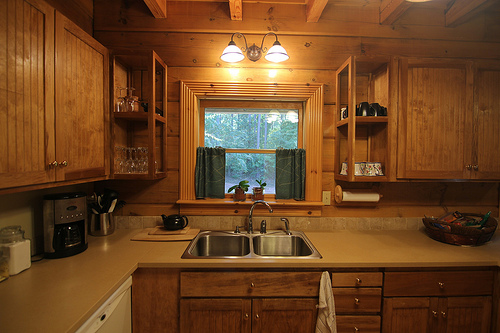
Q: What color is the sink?
A: Silver.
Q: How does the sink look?
A: Clean and polished.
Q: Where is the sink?
A: Between the counter.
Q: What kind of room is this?
A: Kitchen.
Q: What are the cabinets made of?
A: Wood.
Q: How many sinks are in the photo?
A: Two.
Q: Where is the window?
A: Above the sink.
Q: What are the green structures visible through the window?
A: Trees.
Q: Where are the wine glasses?
A: On the shelf to the left of the sink.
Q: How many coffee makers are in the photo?
A: One.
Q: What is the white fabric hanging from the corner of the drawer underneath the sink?
A: Towel.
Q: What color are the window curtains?
A: Green.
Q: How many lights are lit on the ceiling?
A: Two.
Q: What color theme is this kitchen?
A: Brown.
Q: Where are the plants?
A: Window sill.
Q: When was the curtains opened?
A: Morning.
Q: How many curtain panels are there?
A: 2.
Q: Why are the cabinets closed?
A: Not in use.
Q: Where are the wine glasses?
A: Open shelf on left.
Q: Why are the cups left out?
A: Convenience.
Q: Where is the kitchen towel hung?
A: Cabinet drawer edge.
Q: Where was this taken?
A: Kitchen.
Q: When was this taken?
A: Daytime.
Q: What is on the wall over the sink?
A: Light.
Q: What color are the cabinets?
A: Brown.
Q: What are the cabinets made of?
A: Wood.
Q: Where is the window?
A: Over the sink.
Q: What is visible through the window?
A: Trees.